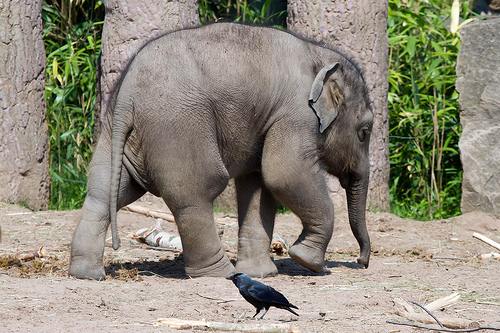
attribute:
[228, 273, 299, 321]
bird — blue, small, black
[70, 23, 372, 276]
elephant — baby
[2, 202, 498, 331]
ground — dirty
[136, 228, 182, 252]
stone — concrete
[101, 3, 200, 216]
tree — large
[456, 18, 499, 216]
rock — gray, large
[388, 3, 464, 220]
foliage — green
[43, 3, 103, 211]
leaves — green